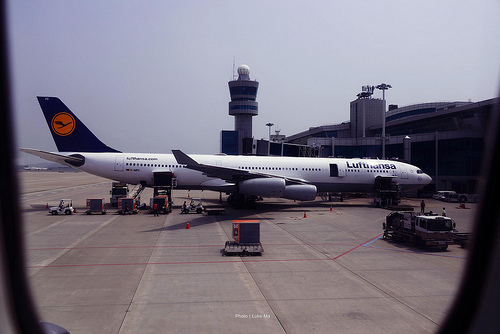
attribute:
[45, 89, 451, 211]
plane — big, white, lufthansa, commercial, large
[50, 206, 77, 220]
truck — red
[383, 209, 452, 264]
vehicle — grouped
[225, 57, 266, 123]
statue — big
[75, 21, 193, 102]
sky — clear, hazy, grey, blue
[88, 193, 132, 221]
objects — far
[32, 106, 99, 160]
tail — blue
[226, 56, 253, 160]
tower — distant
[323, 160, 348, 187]
door — open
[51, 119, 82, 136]
logo — yellow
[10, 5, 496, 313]
photo — daytime, take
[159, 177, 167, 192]
baggage — loaded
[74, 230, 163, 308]
ground — concrete, grey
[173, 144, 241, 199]
wing — large